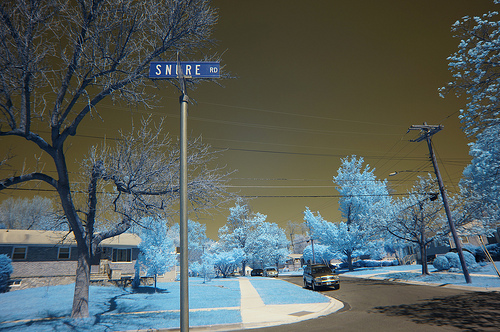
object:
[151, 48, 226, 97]
sign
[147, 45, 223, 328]
pole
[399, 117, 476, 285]
utility pole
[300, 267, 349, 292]
suv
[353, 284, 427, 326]
road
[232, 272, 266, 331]
sidewalk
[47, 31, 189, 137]
foliage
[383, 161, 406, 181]
street light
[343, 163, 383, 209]
tree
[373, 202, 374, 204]
snow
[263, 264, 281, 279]
car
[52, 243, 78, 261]
window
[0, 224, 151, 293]
building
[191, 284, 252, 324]
grass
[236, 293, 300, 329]
corner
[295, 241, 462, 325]
park